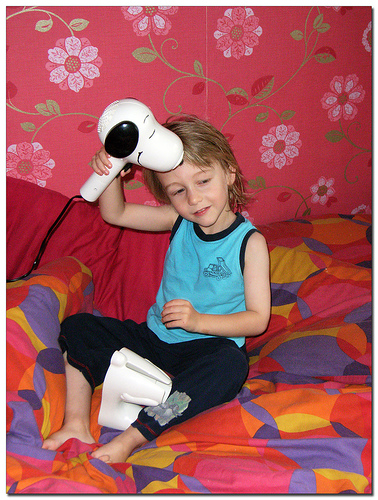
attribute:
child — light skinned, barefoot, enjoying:
[45, 115, 271, 466]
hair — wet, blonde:
[144, 116, 251, 212]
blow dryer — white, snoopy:
[79, 97, 182, 206]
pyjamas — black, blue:
[58, 314, 246, 440]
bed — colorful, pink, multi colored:
[7, 177, 370, 496]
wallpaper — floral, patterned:
[7, 6, 373, 228]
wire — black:
[11, 195, 80, 283]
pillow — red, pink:
[3, 177, 170, 323]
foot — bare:
[45, 425, 96, 449]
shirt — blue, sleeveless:
[147, 214, 259, 348]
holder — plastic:
[98, 347, 171, 432]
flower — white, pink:
[45, 36, 103, 95]